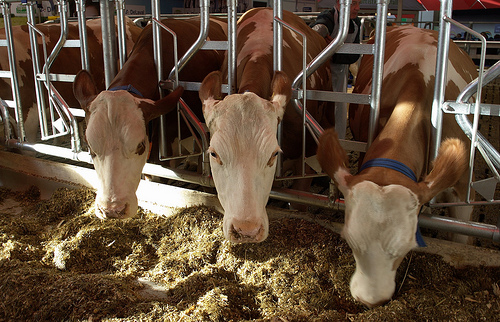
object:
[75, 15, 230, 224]
cow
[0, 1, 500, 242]
fence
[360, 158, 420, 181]
collar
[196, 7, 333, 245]
cow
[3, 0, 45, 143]
gate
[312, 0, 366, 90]
farmer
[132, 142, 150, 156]
eye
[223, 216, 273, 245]
nose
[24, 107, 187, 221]
light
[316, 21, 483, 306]
cow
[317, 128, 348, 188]
ear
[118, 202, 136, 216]
nostril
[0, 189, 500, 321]
grass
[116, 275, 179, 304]
floor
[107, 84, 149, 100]
collar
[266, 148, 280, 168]
spot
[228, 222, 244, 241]
nostrils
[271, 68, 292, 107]
ears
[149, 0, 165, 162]
spoke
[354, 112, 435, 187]
neck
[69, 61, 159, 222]
head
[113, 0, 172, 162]
gates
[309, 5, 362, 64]
shirt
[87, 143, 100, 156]
eyes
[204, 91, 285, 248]
face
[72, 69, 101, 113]
ears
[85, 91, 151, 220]
face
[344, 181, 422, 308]
face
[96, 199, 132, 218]
nose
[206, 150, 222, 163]
eye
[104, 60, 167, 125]
neck